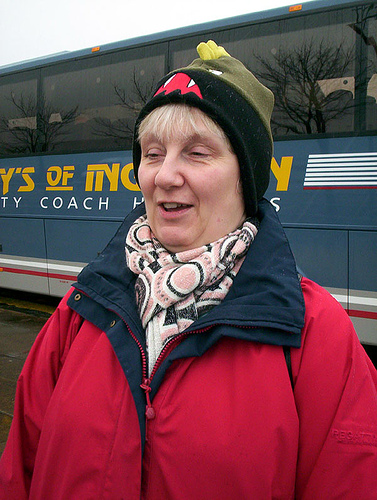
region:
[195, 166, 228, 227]
part of a cheek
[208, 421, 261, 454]
part of a jacket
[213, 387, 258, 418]
part of a jacket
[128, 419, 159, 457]
edge of a jacket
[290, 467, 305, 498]
edge of a jacket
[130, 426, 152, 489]
edge of a zip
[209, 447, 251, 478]
part of a jacket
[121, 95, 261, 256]
an older woman's face.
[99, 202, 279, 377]
a colorful scarf.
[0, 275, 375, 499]
a red jacket on a woman.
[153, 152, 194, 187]
a nose on a woman's face.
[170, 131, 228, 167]
the left eye of a woman.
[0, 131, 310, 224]
a company name on a bus.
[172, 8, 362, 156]
a large window on a bus.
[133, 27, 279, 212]
a hat on a woman's head.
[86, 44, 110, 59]
a light on a bus.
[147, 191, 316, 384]
a blue lapel on a jacket.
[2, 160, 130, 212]
Company logo on the side of a passenger bus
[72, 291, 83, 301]
Snaps in the collar of a winter coat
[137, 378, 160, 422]
Pool string attached to zipper handle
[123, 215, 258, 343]
Scarf worn around the neck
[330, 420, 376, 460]
Logo on the sleeve of a coat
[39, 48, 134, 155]
Window on a passenger bus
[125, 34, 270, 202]
Funny winter hat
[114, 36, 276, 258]
Woman talking about something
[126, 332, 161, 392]
Zipper on a winter coat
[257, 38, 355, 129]
Reflection of a tree in the bus window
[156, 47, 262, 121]
woman has grey cap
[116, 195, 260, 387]
woman has multicolor scarf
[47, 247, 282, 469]
woman has red coat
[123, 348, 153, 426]
red zipper on coat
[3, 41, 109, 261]
large blue passenger bus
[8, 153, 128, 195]
yellow letters on bus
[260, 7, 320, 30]
orange lights on bus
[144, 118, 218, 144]
woman has white hair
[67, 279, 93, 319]
brown buttons on coat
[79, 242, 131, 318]
blue collar on coat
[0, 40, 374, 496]
woman wearing red jacket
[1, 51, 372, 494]
woman wearing green and black hat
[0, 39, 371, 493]
woman wearing pink, black and white scarf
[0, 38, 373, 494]
woman has short blonde hair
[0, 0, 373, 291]
huge coach bus behind woman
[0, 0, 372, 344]
coach bus has yellow letters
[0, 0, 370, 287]
huge coach bus with red stripe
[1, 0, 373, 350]
huge coach bus with white stripes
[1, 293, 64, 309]
yellow painted line under coach bus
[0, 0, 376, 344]
huge coach bus with tinted windows